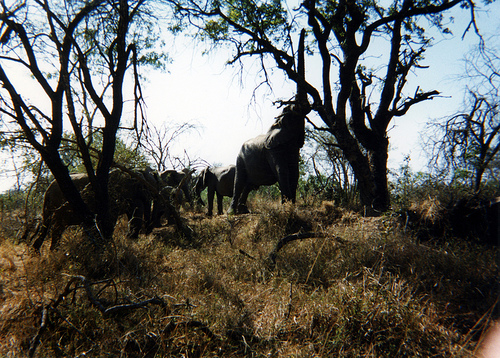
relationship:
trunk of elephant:
[271, 37, 320, 132] [182, 51, 375, 233]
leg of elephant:
[214, 174, 262, 225] [182, 51, 375, 233]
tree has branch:
[261, 30, 428, 215] [223, 12, 420, 94]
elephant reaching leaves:
[182, 51, 375, 233] [232, 6, 306, 58]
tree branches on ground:
[21, 195, 342, 345] [77, 153, 442, 310]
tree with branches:
[261, 30, 428, 215] [182, 16, 398, 79]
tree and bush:
[261, 30, 428, 215] [331, 165, 464, 246]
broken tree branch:
[352, 62, 441, 149] [223, 12, 420, 94]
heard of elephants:
[13, 39, 407, 338] [0, 21, 358, 257]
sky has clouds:
[163, 49, 208, 117] [139, 44, 258, 122]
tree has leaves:
[261, 30, 428, 215] [232, 6, 306, 58]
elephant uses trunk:
[182, 51, 375, 233] [271, 37, 320, 132]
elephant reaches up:
[182, 51, 375, 233] [199, 21, 350, 145]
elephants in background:
[0, 21, 358, 257] [13, 39, 407, 338]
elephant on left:
[182, 51, 375, 233] [86, 128, 263, 245]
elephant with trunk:
[182, 51, 375, 233] [271, 37, 320, 132]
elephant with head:
[182, 51, 375, 233] [268, 84, 351, 154]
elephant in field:
[182, 51, 375, 233] [42, 113, 410, 290]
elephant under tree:
[182, 51, 375, 233] [261, 30, 428, 215]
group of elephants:
[13, 39, 407, 338] [0, 21, 358, 257]